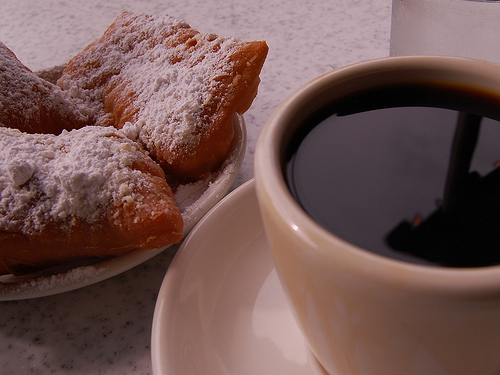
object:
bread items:
[0, 40, 104, 134]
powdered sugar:
[0, 11, 242, 296]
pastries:
[0, 0, 266, 292]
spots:
[0, 0, 271, 316]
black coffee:
[276, 77, 500, 268]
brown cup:
[250, 54, 500, 374]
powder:
[0, 122, 156, 235]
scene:
[0, 0, 495, 375]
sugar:
[3, 158, 32, 187]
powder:
[60, 31, 255, 150]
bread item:
[47, 9, 267, 181]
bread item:
[0, 118, 186, 266]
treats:
[0, 9, 263, 273]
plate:
[131, 178, 323, 375]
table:
[0, 0, 495, 375]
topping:
[0, 118, 135, 229]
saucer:
[135, 171, 323, 375]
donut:
[57, 10, 269, 180]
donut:
[1, 123, 183, 265]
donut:
[0, 38, 94, 132]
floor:
[389, 0, 500, 73]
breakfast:
[0, 0, 500, 375]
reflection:
[375, 100, 495, 276]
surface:
[0, 0, 499, 375]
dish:
[0, 56, 245, 302]